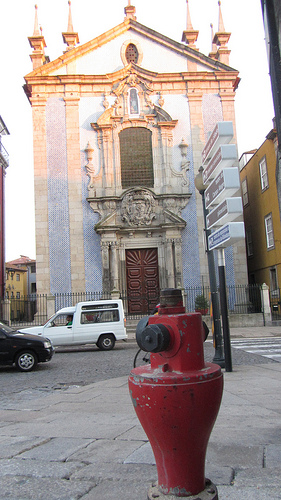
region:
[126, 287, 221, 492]
a red fire hydrant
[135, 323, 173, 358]
a black bolt on a fire hydrant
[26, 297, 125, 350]
a white car on a road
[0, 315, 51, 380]
a black car on a road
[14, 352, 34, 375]
front wheel of a car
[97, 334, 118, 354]
back wheel of a car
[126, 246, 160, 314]
dark brown wooden doors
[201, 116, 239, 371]
a pole full of signs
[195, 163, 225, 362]
a black light pole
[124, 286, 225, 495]
a red fire hydrant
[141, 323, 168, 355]
a black bolt on a hydrant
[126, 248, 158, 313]
a dark wooden door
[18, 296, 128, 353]
a white truck on a road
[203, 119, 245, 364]
signs on a metal pole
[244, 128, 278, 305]
a yellow brick building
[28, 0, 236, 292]
a building made of stone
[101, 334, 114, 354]
a rear tire on a car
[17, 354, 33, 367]
front tire on a car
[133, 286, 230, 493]
a fire hydrant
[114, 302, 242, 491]
the fire hydrant is red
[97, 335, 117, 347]
the back tire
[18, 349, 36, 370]
the front tire of the car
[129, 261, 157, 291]
a door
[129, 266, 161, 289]
the door is brown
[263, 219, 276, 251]
a window on the building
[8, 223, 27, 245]
the sky is clear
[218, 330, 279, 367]
crosswalk on the road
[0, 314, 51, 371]
front end of a car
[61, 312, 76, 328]
person sitting in the car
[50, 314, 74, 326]
driver behind the wheel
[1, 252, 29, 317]
the building is yellow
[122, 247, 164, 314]
large brown door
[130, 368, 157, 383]
red paint is peeling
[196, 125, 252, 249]
a row of signs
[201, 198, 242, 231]
brown and white sign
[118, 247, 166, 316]
a door to a building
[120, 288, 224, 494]
a red fire hydtant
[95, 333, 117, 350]
a wheel of a car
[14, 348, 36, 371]
a wheel of a car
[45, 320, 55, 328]
the rear view mirror of a car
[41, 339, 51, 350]
the headlight of a car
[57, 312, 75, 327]
people inside a car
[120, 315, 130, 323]
a taillight of a car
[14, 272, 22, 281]
a window of a building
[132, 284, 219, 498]
old red fire hydrant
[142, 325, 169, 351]
black cap on hydrant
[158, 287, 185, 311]
dirty cap on hydrant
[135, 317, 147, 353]
black cap on hydrant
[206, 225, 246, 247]
large blue and white sign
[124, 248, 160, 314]
large dark brown door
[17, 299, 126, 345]
small white truck on street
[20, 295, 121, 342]
white car passing in front of building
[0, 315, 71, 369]
black car in front of building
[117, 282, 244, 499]
red fire hydrant on the sidewalk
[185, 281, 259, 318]
metal fence in front of building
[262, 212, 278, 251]
window on the building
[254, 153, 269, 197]
window on the building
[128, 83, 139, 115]
window on the building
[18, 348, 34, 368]
silver rim on the car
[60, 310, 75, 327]
man driving the van